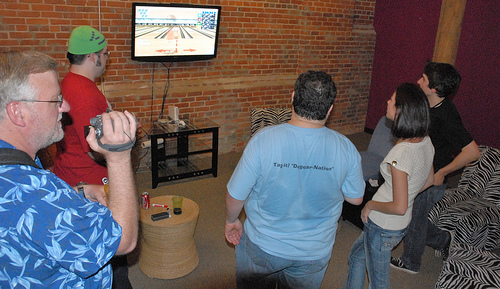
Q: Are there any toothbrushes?
A: No, there are no toothbrushes.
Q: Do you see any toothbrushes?
A: No, there are no toothbrushes.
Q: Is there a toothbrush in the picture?
A: No, there are no toothbrushes.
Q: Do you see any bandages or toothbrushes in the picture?
A: No, there are no toothbrushes or bandages.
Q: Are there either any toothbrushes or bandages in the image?
A: No, there are no toothbrushes or bandages.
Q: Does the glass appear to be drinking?
A: Yes, the glass is drinking.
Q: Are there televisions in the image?
A: Yes, there is a television.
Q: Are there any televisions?
A: Yes, there is a television.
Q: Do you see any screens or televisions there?
A: Yes, there is a television.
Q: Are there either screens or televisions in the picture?
A: Yes, there is a television.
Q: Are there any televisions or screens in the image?
A: Yes, there is a television.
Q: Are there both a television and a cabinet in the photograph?
A: No, there is a television but no cabinets.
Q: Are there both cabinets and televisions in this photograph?
A: No, there is a television but no cabinets.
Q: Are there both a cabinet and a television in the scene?
A: No, there is a television but no cabinets.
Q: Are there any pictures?
A: No, there are no pictures.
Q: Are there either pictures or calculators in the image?
A: No, there are no pictures or calculators.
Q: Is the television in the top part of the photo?
A: Yes, the television is in the top of the image.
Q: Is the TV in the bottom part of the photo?
A: No, the TV is in the top of the image.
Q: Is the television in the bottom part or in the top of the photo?
A: The television is in the top of the image.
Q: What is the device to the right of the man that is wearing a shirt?
A: The device is a television.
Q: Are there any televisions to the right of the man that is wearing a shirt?
A: Yes, there is a television to the right of the man.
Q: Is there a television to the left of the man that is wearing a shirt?
A: No, the television is to the right of the man.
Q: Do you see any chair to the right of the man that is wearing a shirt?
A: No, there is a television to the right of the man.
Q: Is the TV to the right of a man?
A: Yes, the TV is to the right of a man.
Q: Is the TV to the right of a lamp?
A: No, the TV is to the right of a man.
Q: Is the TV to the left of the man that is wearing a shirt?
A: No, the TV is to the right of the man.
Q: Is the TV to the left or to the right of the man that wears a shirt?
A: The TV is to the right of the man.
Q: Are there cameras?
A: Yes, there is a camera.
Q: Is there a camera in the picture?
A: Yes, there is a camera.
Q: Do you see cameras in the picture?
A: Yes, there is a camera.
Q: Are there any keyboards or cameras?
A: Yes, there is a camera.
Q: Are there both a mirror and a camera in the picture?
A: No, there is a camera but no mirrors.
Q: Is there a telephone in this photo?
A: No, there are no phones.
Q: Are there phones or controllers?
A: No, there are no phones or controllers.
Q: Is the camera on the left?
A: Yes, the camera is on the left of the image.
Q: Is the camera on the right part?
A: No, the camera is on the left of the image.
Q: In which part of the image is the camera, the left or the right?
A: The camera is on the left of the image.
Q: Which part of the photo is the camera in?
A: The camera is on the left of the image.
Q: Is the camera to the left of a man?
A: Yes, the camera is to the left of a man.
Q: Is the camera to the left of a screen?
A: No, the camera is to the left of a man.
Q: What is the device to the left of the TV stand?
A: The device is a camera.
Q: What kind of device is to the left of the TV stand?
A: The device is a camera.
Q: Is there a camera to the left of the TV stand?
A: Yes, there is a camera to the left of the TV stand.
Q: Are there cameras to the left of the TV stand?
A: Yes, there is a camera to the left of the TV stand.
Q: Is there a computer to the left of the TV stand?
A: No, there is a camera to the left of the TV stand.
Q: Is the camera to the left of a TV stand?
A: Yes, the camera is to the left of a TV stand.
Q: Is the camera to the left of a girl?
A: No, the camera is to the left of a TV stand.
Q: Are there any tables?
A: Yes, there is a table.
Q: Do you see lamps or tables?
A: Yes, there is a table.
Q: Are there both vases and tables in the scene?
A: No, there is a table but no vases.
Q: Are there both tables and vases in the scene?
A: No, there is a table but no vases.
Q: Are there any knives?
A: No, there are no knives.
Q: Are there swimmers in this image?
A: No, there are no swimmers.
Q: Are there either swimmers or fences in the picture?
A: No, there are no swimmers or fences.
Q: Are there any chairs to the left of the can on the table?
A: No, there is a man to the left of the can.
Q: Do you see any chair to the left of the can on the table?
A: No, there is a man to the left of the can.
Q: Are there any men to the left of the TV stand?
A: Yes, there is a man to the left of the TV stand.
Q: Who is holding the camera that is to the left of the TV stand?
A: The man is holding the camera.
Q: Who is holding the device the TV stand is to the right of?
A: The man is holding the camera.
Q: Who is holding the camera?
A: The man is holding the camera.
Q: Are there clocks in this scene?
A: No, there are no clocks.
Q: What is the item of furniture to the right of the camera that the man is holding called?
A: The piece of furniture is a TV stand.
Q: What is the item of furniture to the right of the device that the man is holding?
A: The piece of furniture is a TV stand.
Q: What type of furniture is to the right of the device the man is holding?
A: The piece of furniture is a TV stand.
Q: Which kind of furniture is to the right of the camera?
A: The piece of furniture is a TV stand.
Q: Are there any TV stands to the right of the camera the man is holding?
A: Yes, there is a TV stand to the right of the camera.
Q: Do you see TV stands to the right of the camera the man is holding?
A: Yes, there is a TV stand to the right of the camera.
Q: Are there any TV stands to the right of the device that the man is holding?
A: Yes, there is a TV stand to the right of the camera.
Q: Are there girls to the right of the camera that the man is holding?
A: No, there is a TV stand to the right of the camera.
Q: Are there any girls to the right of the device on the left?
A: No, there is a TV stand to the right of the camera.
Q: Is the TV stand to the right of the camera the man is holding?
A: Yes, the TV stand is to the right of the camera.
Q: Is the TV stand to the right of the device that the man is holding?
A: Yes, the TV stand is to the right of the camera.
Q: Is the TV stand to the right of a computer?
A: No, the TV stand is to the right of the camera.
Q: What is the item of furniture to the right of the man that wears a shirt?
A: The piece of furniture is a TV stand.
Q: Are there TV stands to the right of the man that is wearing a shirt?
A: Yes, there is a TV stand to the right of the man.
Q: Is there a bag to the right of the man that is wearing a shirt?
A: No, there is a TV stand to the right of the man.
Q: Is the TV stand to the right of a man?
A: Yes, the TV stand is to the right of a man.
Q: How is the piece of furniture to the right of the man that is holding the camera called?
A: The piece of furniture is a TV stand.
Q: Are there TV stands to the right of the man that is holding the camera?
A: Yes, there is a TV stand to the right of the man.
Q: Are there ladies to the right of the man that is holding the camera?
A: No, there is a TV stand to the right of the man.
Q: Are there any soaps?
A: No, there are no soaps.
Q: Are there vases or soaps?
A: No, there are no soaps or vases.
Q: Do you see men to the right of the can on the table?
A: Yes, there is a man to the right of the can.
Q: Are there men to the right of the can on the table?
A: Yes, there is a man to the right of the can.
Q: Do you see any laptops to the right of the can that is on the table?
A: No, there is a man to the right of the can.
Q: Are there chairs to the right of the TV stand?
A: No, there is a man to the right of the TV stand.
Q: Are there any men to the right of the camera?
A: Yes, there is a man to the right of the camera.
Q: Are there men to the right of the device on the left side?
A: Yes, there is a man to the right of the camera.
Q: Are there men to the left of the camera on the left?
A: No, the man is to the right of the camera.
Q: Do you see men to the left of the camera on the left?
A: No, the man is to the right of the camera.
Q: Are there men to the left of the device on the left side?
A: No, the man is to the right of the camera.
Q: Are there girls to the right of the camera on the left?
A: No, there is a man to the right of the camera.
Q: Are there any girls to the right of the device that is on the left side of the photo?
A: No, there is a man to the right of the camera.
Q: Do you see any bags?
A: No, there are no bags.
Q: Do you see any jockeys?
A: No, there are no jockeys.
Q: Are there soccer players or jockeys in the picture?
A: No, there are no jockeys or soccer players.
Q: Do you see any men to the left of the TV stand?
A: Yes, there is a man to the left of the TV stand.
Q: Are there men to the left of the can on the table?
A: Yes, there is a man to the left of the can.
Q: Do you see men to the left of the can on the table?
A: Yes, there is a man to the left of the can.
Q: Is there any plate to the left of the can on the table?
A: No, there is a man to the left of the can.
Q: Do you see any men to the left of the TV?
A: Yes, there is a man to the left of the TV.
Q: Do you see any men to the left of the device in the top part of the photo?
A: Yes, there is a man to the left of the TV.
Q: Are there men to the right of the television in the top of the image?
A: No, the man is to the left of the television.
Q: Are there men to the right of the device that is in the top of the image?
A: No, the man is to the left of the television.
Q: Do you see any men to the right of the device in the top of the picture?
A: No, the man is to the left of the television.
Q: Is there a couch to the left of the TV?
A: No, there is a man to the left of the TV.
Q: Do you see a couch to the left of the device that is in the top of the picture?
A: No, there is a man to the left of the TV.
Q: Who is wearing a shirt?
A: The man is wearing a shirt.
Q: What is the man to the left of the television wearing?
A: The man is wearing a shirt.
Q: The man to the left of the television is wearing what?
A: The man is wearing a shirt.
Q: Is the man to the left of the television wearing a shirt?
A: Yes, the man is wearing a shirt.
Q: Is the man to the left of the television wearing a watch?
A: No, the man is wearing a shirt.